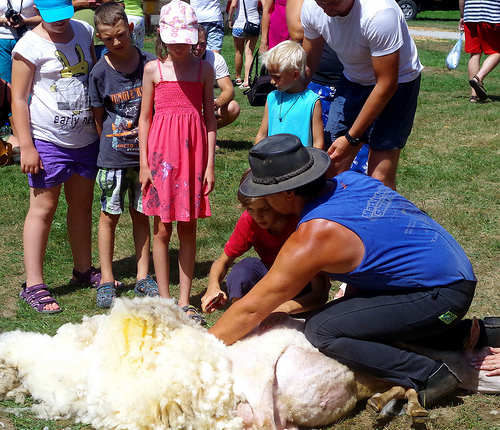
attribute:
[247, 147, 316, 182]
hat — black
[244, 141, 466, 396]
man — light skinned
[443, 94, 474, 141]
grass — in area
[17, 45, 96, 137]
shirt — pink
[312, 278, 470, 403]
pants — black